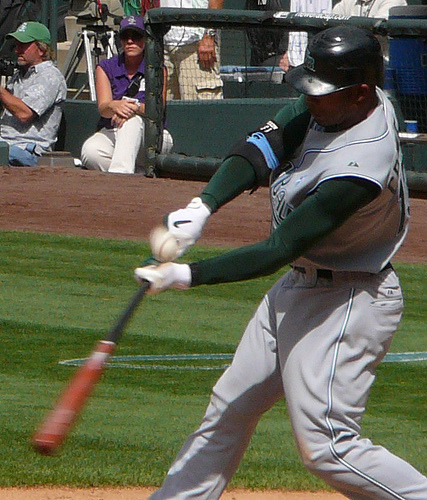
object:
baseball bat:
[30, 253, 162, 455]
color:
[33, 340, 121, 458]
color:
[108, 257, 166, 345]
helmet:
[282, 24, 384, 95]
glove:
[167, 195, 211, 260]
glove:
[137, 258, 193, 290]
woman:
[77, 15, 169, 176]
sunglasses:
[121, 30, 144, 43]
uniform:
[150, 86, 427, 499]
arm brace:
[231, 108, 289, 207]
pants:
[148, 253, 423, 500]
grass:
[2, 232, 427, 487]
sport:
[3, 0, 419, 493]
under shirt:
[187, 81, 383, 286]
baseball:
[146, 227, 182, 265]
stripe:
[327, 284, 407, 497]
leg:
[276, 259, 427, 496]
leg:
[150, 269, 298, 499]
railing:
[140, 1, 426, 185]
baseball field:
[2, 156, 427, 497]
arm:
[188, 175, 380, 286]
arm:
[195, 94, 318, 216]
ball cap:
[5, 21, 53, 43]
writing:
[17, 23, 33, 33]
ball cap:
[118, 16, 150, 41]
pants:
[78, 115, 147, 178]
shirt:
[93, 51, 164, 131]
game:
[5, 15, 422, 494]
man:
[0, 19, 68, 169]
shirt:
[2, 56, 70, 156]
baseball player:
[135, 21, 427, 499]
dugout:
[5, 0, 427, 166]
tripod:
[61, 25, 128, 100]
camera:
[76, 0, 127, 38]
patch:
[1, 166, 426, 265]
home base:
[62, 322, 426, 385]